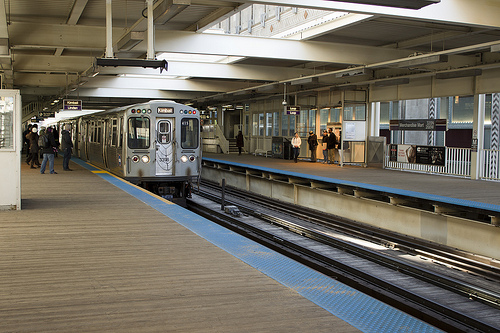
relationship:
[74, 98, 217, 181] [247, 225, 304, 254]
train on tracks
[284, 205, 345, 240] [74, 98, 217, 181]
tracks beside train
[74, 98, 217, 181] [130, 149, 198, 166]
train has headlights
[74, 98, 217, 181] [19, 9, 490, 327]
train in station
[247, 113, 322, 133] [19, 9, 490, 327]
windows in train station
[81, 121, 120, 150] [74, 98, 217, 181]
windows on train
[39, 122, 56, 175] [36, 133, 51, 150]
person carries backpack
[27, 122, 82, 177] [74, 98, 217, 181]
people beside train